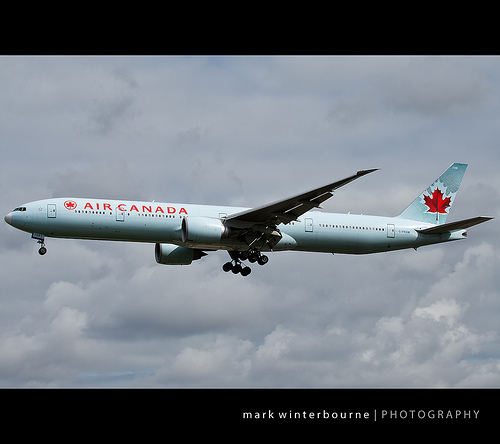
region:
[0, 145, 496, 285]
A commercial airplane in the air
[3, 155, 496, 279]
an Air Canada airplane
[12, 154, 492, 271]
airplane is flying in the sky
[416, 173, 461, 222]
red maple leaf on plane's tail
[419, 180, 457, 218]
logo for air canada on tail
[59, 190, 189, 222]
air canada written in red on plane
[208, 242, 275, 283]
plane's landing gear is out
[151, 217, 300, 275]
plane has two engines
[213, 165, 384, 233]
wing of the plane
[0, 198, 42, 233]
cockpit of the plane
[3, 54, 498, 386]
sky is cloudy and gray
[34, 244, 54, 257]
Front wheel of the plane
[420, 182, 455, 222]
A red leaf symbolizing country of canada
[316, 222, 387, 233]
Small windows of the left side of the plane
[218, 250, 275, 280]
Three pairs of the planes' wheel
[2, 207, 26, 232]
White tip of the front of plane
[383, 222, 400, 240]
Back door of the left side of the plane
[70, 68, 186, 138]
A gray fog at the top of the plane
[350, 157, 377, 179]
Tip of the airplanes' wing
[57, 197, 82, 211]
There is a red border around the red leaf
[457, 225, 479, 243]
Tip of the airplanes' tail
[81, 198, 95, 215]
The letter is orange.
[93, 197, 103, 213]
The letter is orange.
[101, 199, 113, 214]
The letter is orange.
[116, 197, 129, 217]
The letter is orange.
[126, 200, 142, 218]
The letter is orange.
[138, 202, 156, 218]
The letter is orange.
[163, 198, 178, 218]
The letter is orange.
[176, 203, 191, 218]
The letter is orange.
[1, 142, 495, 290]
The plane has a maple leaf on it.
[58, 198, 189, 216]
the name and logo of a business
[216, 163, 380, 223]
the wing of an airplane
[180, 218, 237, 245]
the engine of an airplane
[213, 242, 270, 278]
a plane's rear landing gear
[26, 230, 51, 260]
the nose landing gear on a plane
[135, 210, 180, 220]
passenger windows on an airplane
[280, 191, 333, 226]
flaps on an airplane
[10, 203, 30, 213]
an airplane's cockpit windows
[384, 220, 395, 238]
the side door on an airplane